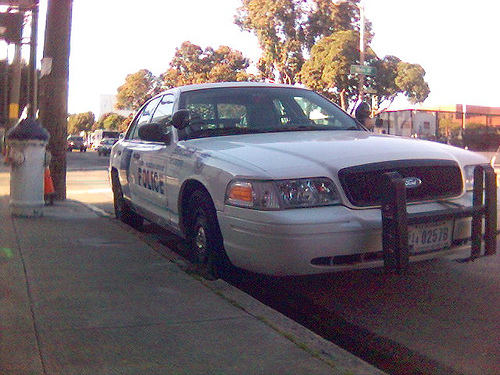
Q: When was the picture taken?
A: The street.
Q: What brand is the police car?
A: Ford.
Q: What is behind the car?
A: Trees.